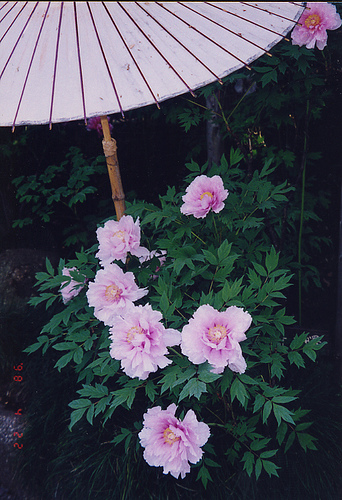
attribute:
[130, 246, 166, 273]
flower — YELLOW, PINK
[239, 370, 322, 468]
green leaves — healthy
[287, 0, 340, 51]
flower — PINK, YELLOW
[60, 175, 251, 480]
flowers — PINK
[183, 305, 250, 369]
flower — pink, yellow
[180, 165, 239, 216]
flower — PRETTY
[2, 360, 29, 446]
umbrella — pink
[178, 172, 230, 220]
flower — PINK, YELLOW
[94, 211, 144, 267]
flower — PINK, YELLOW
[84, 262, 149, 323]
flower — PINK, YELLOW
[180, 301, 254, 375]
flower — PINK, YELLOW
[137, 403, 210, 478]
flower — beautiful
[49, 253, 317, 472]
bush — YELLOW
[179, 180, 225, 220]
flower — pink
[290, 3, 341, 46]
flower — PINK, YELLOW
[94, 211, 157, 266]
flower — PINK, YELLOW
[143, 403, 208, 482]
flower — pink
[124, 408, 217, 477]
flower — pink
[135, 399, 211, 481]
flower — PINK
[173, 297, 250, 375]
flower — YELLOW, PINK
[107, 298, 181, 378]
flower — YELLOW, PINK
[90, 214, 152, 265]
flower — YELLOW, PINK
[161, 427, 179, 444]
center — YELLOW